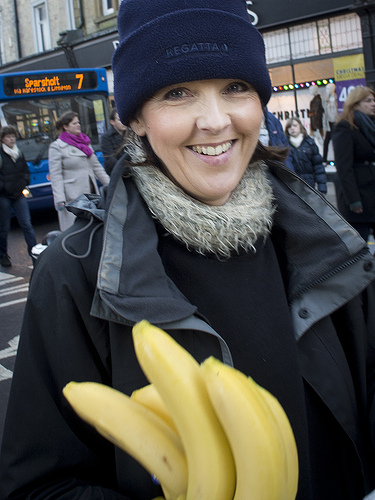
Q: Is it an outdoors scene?
A: Yes, it is outdoors.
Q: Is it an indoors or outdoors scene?
A: It is outdoors.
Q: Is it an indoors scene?
A: No, it is outdoors.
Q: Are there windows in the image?
A: Yes, there is a window.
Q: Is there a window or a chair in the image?
A: Yes, there is a window.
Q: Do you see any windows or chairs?
A: Yes, there is a window.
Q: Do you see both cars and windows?
A: No, there is a window but no cars.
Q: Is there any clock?
A: No, there are no clocks.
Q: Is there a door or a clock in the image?
A: No, there are no clocks or doors.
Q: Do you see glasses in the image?
A: No, there are no glasses.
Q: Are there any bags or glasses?
A: No, there are no glasses or bags.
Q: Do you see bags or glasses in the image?
A: No, there are no glasses or bags.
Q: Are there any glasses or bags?
A: No, there are no glasses or bags.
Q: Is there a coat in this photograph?
A: Yes, there is a coat.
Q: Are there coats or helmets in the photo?
A: Yes, there is a coat.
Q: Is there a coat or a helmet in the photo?
A: Yes, there is a coat.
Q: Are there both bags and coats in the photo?
A: No, there is a coat but no bags.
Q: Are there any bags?
A: No, there are no bags.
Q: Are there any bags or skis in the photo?
A: No, there are no bags or skis.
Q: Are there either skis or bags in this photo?
A: No, there are no bags or skis.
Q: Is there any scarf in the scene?
A: Yes, there is a scarf.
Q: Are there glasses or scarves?
A: Yes, there is a scarf.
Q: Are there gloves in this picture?
A: No, there are no gloves.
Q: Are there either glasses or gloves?
A: No, there are no gloves or glasses.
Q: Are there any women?
A: Yes, there is a woman.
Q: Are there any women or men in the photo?
A: Yes, there is a woman.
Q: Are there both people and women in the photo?
A: Yes, there are both a woman and a person.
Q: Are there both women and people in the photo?
A: Yes, there are both a woman and a person.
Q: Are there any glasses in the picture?
A: No, there are no glasses.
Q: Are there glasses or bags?
A: No, there are no glasses or bags.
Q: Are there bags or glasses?
A: No, there are no glasses or bags.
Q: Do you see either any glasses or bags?
A: No, there are no glasses or bags.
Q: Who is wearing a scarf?
A: The woman is wearing a scarf.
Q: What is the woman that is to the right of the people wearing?
A: The woman is wearing a scarf.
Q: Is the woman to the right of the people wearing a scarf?
A: Yes, the woman is wearing a scarf.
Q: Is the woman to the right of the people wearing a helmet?
A: No, the woman is wearing a scarf.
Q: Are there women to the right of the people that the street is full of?
A: Yes, there is a woman to the right of the people.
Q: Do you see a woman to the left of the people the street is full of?
A: No, the woman is to the right of the people.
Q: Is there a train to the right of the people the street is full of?
A: No, there is a woman to the right of the people.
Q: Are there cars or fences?
A: No, there are no cars or fences.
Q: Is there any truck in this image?
A: No, there are no trucks.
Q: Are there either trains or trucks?
A: No, there are no trucks or trains.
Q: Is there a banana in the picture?
A: Yes, there is a banana.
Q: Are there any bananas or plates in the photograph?
A: Yes, there is a banana.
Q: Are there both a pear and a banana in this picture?
A: No, there is a banana but no pears.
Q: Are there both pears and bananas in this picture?
A: No, there is a banana but no pears.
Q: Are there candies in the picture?
A: No, there are no candies.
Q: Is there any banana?
A: Yes, there is a banana.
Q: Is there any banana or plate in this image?
A: Yes, there is a banana.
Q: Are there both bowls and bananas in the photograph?
A: No, there is a banana but no bowls.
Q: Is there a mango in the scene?
A: No, there are no mangoes.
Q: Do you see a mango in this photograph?
A: No, there are no mangoes.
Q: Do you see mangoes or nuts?
A: No, there are no mangoes or nuts.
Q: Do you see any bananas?
A: Yes, there is a banana.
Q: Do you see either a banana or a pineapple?
A: Yes, there is a banana.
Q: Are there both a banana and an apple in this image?
A: No, there is a banana but no apples.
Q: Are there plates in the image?
A: No, there are no plates.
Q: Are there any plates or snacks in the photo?
A: No, there are no plates or snacks.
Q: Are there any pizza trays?
A: No, there are no pizza trays.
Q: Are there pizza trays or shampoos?
A: No, there are no pizza trays or shampoos.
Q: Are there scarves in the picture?
A: Yes, there is a scarf.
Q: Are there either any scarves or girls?
A: Yes, there is a scarf.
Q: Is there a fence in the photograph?
A: No, there are no fences.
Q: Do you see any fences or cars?
A: No, there are no fences or cars.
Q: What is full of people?
A: The street is full of people.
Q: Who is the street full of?
A: The street is full of people.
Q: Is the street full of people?
A: Yes, the street is full of people.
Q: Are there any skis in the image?
A: No, there are no skis.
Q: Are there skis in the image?
A: No, there are no skis.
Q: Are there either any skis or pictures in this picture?
A: No, there are no skis or pictures.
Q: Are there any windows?
A: Yes, there is a window.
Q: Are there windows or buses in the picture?
A: Yes, there is a window.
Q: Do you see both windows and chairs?
A: No, there is a window but no chairs.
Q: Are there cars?
A: No, there are no cars.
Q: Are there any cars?
A: No, there are no cars.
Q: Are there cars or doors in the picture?
A: No, there are no cars or doors.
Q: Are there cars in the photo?
A: No, there are no cars.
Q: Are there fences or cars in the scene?
A: No, there are no cars or fences.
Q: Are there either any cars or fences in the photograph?
A: No, there are no cars or fences.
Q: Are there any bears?
A: No, there are no bears.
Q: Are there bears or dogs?
A: No, there are no bears or dogs.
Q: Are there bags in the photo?
A: No, there are no bags.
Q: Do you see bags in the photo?
A: No, there are no bags.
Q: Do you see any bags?
A: No, there are no bags.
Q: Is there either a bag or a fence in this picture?
A: No, there are no bags or fences.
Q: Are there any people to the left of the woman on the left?
A: Yes, there are people to the left of the woman.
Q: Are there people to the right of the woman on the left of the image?
A: No, the people are to the left of the woman.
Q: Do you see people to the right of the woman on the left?
A: No, the people are to the left of the woman.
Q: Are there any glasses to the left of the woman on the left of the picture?
A: No, there are people to the left of the woman.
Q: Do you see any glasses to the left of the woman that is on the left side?
A: No, there are people to the left of the woman.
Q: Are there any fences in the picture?
A: No, there are no fences.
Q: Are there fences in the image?
A: No, there are no fences.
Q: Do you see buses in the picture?
A: Yes, there is a bus.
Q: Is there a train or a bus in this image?
A: Yes, there is a bus.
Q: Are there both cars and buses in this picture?
A: No, there is a bus but no cars.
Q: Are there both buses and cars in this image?
A: No, there is a bus but no cars.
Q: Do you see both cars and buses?
A: No, there is a bus but no cars.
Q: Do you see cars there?
A: No, there are no cars.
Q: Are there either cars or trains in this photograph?
A: No, there are no cars or trains.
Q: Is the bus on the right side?
A: No, the bus is on the left of the image.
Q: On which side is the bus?
A: The bus is on the left of the image.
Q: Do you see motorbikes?
A: No, there are no motorbikes.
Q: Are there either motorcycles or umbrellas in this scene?
A: No, there are no motorcycles or umbrellas.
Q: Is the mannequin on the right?
A: Yes, the mannequin is on the right of the image.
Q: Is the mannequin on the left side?
A: No, the mannequin is on the right of the image.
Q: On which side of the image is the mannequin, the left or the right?
A: The mannequin is on the right of the image.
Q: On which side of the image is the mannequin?
A: The mannequin is on the right of the image.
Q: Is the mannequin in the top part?
A: Yes, the mannequin is in the top of the image.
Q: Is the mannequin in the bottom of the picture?
A: No, the mannequin is in the top of the image.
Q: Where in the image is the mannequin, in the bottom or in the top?
A: The mannequin is in the top of the image.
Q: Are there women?
A: Yes, there is a woman.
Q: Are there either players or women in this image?
A: Yes, there is a woman.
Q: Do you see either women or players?
A: Yes, there is a woman.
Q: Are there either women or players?
A: Yes, there is a woman.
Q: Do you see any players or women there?
A: Yes, there is a woman.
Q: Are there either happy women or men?
A: Yes, there is a happy woman.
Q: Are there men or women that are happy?
A: Yes, the woman is happy.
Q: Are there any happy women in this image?
A: Yes, there is a happy woman.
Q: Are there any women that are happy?
A: Yes, there is a woman that is happy.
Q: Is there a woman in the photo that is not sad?
A: Yes, there is a happy woman.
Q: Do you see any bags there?
A: No, there are no bags.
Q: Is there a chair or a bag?
A: No, there are no bags or chairs.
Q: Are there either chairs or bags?
A: No, there are no bags or chairs.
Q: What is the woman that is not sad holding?
A: The woman is holding the banana.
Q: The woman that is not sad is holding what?
A: The woman is holding the banana.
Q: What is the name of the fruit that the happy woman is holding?
A: The fruit is a banana.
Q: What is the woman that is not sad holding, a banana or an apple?
A: The woman is holding a banana.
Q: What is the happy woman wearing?
A: The woman is wearing a scarf.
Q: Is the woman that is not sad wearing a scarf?
A: Yes, the woman is wearing a scarf.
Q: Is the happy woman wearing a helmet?
A: No, the woman is wearing a scarf.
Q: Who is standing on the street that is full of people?
A: The woman is standing on the street.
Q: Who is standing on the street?
A: The woman is standing on the street.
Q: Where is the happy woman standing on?
A: The woman is standing on the street.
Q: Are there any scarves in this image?
A: Yes, there is a scarf.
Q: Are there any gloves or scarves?
A: Yes, there is a scarf.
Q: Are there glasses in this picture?
A: No, there are no glasses.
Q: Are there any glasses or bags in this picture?
A: No, there are no glasses or bags.